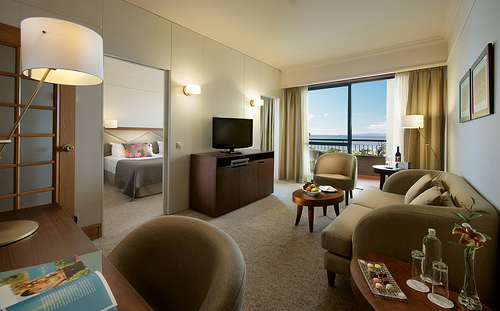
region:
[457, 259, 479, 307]
A glass vase.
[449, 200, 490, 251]
A flower in a vase.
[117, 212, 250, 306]
A brown seat.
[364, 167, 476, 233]
A brown couch in the photo.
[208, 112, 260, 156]
A flat screen television monitor.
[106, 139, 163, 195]
A bed in the photo.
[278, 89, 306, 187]
Curtains in the picture.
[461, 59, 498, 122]
Wall hangings in the photo.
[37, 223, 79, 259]
A wooden table in the room.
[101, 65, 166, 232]
An opened door in the room.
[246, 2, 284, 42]
part of a ceiling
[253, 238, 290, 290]
part of a floor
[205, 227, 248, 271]
edge of a chair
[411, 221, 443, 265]
part of a bottle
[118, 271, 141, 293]
edge of a table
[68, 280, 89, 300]
part of a magazine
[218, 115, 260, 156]
part of a screen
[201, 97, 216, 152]
edge of the tv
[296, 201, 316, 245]
part of a stand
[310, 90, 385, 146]
The sky is blue and clear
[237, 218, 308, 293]
The carpet is tan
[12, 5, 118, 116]
The light is on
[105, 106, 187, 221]
There is a bed in the other room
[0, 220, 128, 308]
The magazine is open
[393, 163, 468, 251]
The couch has pillows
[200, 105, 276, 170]
The tv is off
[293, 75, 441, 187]
The door is closed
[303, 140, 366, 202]
The chair is tan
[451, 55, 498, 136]
There are pictures on the wall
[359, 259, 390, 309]
tray of assorted candies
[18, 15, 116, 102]
lit white table lamp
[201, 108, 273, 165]
black flat screen t.v.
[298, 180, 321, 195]
bowl of assorted fruits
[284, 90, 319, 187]
tan and cream window covers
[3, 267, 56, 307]
open magazine with photo of family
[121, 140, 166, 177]
pink and brown floral design pillow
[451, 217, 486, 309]
single lilly in clear vase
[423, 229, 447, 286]
clear bottle of water and empty glass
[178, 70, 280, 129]
small lit wall fixture lights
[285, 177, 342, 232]
a small wooden coffee table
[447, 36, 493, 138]
two framed objects on wall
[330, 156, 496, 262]
a brown couch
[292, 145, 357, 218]
chair near coffee table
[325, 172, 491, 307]
small side table beside couch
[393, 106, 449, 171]
floor lamp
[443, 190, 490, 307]
flower in clear vase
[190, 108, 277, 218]
flat screen television on cabinet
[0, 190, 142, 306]
open magazine on table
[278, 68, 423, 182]
scenic view seen through windows